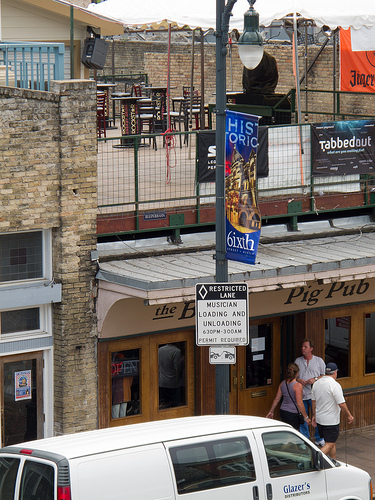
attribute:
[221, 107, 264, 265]
flag — large, blue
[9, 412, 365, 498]
van — white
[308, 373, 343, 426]
shirt — white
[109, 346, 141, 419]
sign — partially lit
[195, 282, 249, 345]
sign — black, white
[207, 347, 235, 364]
sign — white, black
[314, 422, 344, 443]
shorts — black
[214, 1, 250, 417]
pole — tall